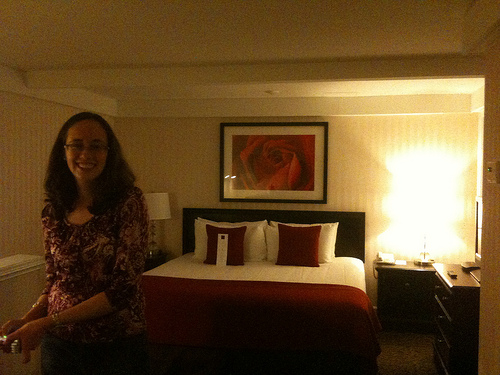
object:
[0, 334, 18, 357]
camera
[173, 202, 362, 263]
headboard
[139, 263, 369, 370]
blanket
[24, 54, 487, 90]
beam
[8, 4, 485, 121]
ceiling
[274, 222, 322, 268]
pillow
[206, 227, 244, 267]
pillow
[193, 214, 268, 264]
pillow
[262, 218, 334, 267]
pillow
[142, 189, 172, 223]
lamp shade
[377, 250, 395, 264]
phone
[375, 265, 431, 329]
cabinet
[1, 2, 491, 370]
bedroom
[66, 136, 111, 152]
glasses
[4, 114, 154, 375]
woman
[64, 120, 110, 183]
face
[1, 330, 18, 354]
remote control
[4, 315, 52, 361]
hands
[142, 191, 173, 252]
lamp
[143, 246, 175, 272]
nightstand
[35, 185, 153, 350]
dress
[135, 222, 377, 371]
comforter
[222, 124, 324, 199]
painting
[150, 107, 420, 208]
wall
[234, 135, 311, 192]
rose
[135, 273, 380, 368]
bed covering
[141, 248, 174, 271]
table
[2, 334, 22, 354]
item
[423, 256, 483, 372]
dresser table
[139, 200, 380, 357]
bed